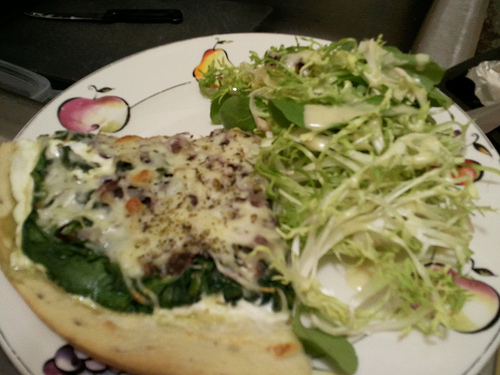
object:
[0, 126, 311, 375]
pizza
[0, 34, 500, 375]
food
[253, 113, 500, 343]
vegetable sprouts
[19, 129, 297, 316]
spinach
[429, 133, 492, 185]
apple design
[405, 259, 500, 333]
apple design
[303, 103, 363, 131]
sauce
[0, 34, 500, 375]
salad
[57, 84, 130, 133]
apple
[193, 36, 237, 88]
pear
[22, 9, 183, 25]
knife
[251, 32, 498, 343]
dressing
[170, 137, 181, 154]
meat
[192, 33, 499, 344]
sprouts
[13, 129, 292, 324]
cheese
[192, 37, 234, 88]
pear design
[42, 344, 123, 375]
grape image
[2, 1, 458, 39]
background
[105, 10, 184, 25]
black handle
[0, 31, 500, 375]
plate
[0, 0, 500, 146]
table